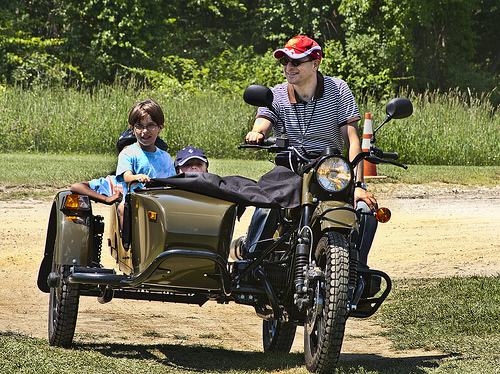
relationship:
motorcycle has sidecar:
[242, 82, 417, 373] [36, 161, 306, 359]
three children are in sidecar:
[70, 97, 214, 258] [36, 161, 306, 359]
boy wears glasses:
[113, 94, 180, 195] [129, 121, 159, 136]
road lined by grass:
[4, 185, 496, 332] [0, 146, 495, 197]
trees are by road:
[4, 8, 492, 89] [4, 185, 496, 332]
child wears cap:
[171, 144, 217, 179] [169, 140, 215, 171]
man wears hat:
[243, 33, 386, 206] [262, 31, 324, 64]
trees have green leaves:
[4, 8, 492, 89] [87, 19, 138, 64]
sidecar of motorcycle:
[36, 161, 306, 359] [242, 82, 417, 373]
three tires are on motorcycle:
[46, 225, 355, 369] [242, 82, 417, 373]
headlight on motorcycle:
[307, 150, 362, 195] [242, 82, 417, 373]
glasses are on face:
[129, 121, 159, 136] [131, 114, 161, 149]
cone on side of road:
[359, 109, 381, 179] [4, 185, 496, 332]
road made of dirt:
[4, 185, 496, 332] [416, 206, 479, 265]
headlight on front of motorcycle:
[307, 150, 362, 195] [242, 82, 417, 373]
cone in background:
[359, 109, 381, 179] [21, 76, 493, 181]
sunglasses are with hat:
[274, 54, 319, 68] [262, 31, 324, 64]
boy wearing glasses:
[113, 94, 180, 195] [129, 121, 159, 136]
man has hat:
[243, 33, 386, 206] [262, 31, 324, 64]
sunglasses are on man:
[274, 54, 319, 68] [243, 33, 386, 206]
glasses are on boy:
[129, 121, 159, 136] [113, 94, 180, 195]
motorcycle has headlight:
[242, 82, 417, 373] [307, 150, 362, 195]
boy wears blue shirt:
[113, 94, 180, 195] [112, 146, 186, 185]